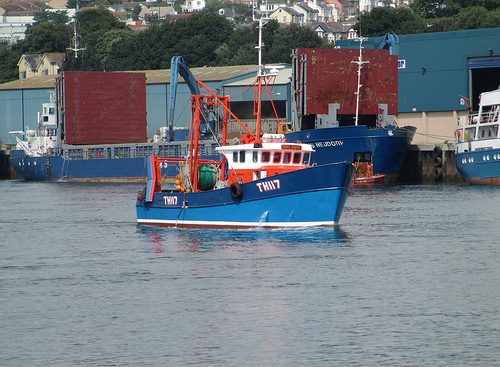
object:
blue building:
[0, 63, 292, 141]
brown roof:
[0, 62, 275, 91]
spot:
[0, 192, 500, 367]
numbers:
[256, 179, 281, 192]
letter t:
[256, 182, 263, 192]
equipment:
[142, 77, 228, 194]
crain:
[164, 52, 214, 144]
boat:
[9, 111, 418, 190]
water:
[0, 180, 497, 367]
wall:
[64, 135, 166, 178]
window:
[232, 150, 239, 162]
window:
[238, 150, 246, 164]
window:
[250, 150, 258, 163]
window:
[259, 150, 271, 164]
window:
[272, 151, 282, 163]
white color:
[134, 219, 338, 227]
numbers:
[164, 196, 178, 206]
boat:
[135, 72, 356, 232]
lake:
[0, 174, 496, 367]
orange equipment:
[145, 94, 231, 202]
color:
[191, 220, 246, 229]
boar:
[135, 217, 337, 230]